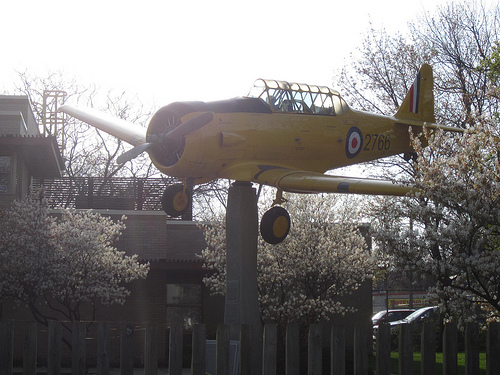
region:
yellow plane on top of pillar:
[60, 60, 461, 363]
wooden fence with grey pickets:
[0, 315, 495, 370]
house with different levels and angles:
[5, 95, 365, 321]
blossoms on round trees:
[1, 125, 491, 315]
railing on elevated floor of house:
[30, 162, 180, 214]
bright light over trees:
[0, 5, 495, 215]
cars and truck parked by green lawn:
[371, 285, 491, 367]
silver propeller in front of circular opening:
[112, 105, 208, 185]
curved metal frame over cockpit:
[245, 66, 341, 111]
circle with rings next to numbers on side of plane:
[336, 125, 394, 155]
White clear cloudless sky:
[181, 7, 297, 49]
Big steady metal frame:
[41, 91, 63, 127]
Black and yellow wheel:
[255, 203, 305, 248]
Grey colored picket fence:
[98, 325, 204, 366]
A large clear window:
[164, 278, 204, 317]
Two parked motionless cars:
[381, 303, 424, 320]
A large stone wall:
[222, 198, 261, 325]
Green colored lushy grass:
[415, 353, 422, 372]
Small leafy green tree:
[8, 215, 112, 302]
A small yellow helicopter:
[132, 95, 449, 164]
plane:
[30, 68, 442, 201]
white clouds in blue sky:
[80, 72, 101, 88]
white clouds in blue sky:
[101, 34, 167, 76]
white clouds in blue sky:
[26, 31, 83, 77]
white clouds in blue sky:
[269, 27, 310, 98]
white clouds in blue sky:
[149, 47, 179, 70]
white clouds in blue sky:
[76, 36, 104, 71]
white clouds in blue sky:
[23, 16, 76, 62]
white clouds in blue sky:
[98, 15, 151, 52]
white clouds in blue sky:
[57, 54, 139, 134]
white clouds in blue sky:
[61, 30, 101, 78]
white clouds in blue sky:
[129, 26, 160, 54]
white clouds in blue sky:
[201, 33, 233, 61]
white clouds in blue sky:
[47, 20, 88, 56]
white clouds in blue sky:
[313, 20, 327, 38]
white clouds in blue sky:
[175, 7, 197, 32]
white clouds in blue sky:
[96, 11, 110, 32]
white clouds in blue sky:
[142, 17, 177, 52]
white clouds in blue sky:
[71, 35, 95, 62]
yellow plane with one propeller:
[56, 58, 469, 243]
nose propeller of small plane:
[111, 98, 221, 190]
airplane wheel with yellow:
[258, 207, 295, 247]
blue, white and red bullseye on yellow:
[341, 122, 368, 161]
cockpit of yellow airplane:
[246, 71, 356, 124]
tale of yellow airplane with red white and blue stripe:
[392, 60, 486, 159]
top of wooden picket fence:
[21, 316, 498, 374]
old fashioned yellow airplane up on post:
[53, 60, 473, 352]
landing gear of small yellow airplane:
[158, 178, 295, 249]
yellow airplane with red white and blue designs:
[51, 57, 481, 247]